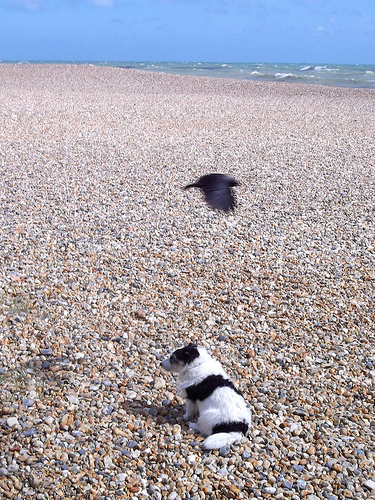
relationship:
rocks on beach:
[1, 64, 374, 499] [0, 60, 375, 498]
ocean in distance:
[0, 59, 373, 88] [1, 59, 373, 88]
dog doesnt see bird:
[159, 343, 251, 451] [181, 172, 241, 216]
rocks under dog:
[1, 64, 374, 499] [159, 343, 251, 451]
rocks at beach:
[1, 64, 374, 499] [0, 60, 375, 498]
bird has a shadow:
[181, 172, 241, 216] [3, 354, 81, 403]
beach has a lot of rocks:
[0, 60, 375, 498] [1, 64, 374, 499]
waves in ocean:
[119, 62, 373, 84] [0, 59, 373, 88]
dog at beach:
[159, 343, 251, 451] [0, 60, 375, 498]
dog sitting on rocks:
[159, 343, 251, 451] [1, 64, 374, 499]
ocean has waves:
[0, 59, 373, 88] [119, 62, 373, 84]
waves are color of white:
[119, 62, 373, 84] [131, 62, 375, 84]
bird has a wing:
[181, 172, 241, 216] [200, 185, 238, 213]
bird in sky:
[181, 172, 241, 216] [0, 0, 374, 67]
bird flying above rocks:
[181, 172, 241, 216] [1, 64, 374, 499]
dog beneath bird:
[159, 343, 251, 451] [181, 172, 241, 216]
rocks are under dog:
[1, 64, 374, 499] [159, 343, 251, 451]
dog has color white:
[159, 343, 251, 451] [160, 343, 251, 450]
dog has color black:
[159, 343, 251, 451] [160, 343, 251, 451]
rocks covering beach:
[1, 64, 374, 499] [0, 60, 375, 498]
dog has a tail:
[159, 343, 251, 451] [200, 432, 243, 450]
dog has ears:
[159, 343, 251, 451] [183, 343, 200, 362]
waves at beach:
[119, 62, 373, 84] [0, 60, 375, 498]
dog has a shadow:
[159, 343, 251, 451] [120, 398, 199, 430]